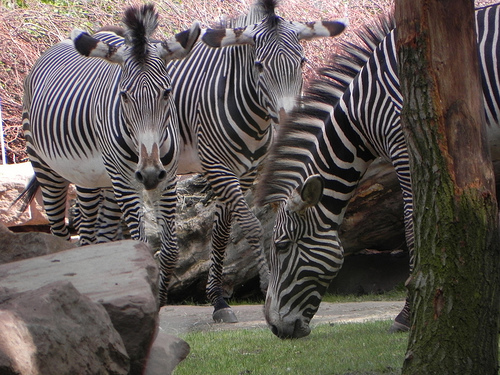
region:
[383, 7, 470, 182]
the trunk is sliced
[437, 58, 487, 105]
the trunk is sliced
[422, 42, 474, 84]
the trunk is sliced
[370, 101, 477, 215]
the trunk is sliced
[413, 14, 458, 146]
the trunk is sliced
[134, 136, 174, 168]
Brown markings on zebra's face.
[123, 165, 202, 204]
Zebra has black nose.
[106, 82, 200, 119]
Zebra has dark eyes.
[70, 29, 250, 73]
Zebra has black and white ears.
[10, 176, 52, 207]
Zebra has black hair on tail.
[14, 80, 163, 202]
Zebra is covered in stripes.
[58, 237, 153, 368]
Large gray rocks near zebras.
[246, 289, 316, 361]
Zebra is bending over to eat.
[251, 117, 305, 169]
Zebra has black and white hair on head.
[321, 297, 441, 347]
Zebra is standing in grass.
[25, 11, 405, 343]
Three zebras are in the picture.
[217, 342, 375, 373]
The grass is green.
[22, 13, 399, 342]
The zebras are black and white.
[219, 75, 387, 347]
The zebra is eating.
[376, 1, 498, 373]
A tree trunk.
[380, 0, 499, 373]
The tree trunk is brown.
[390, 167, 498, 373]
The tree trunk has moss on it.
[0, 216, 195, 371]
The rocks are gray.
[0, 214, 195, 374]
The rocks are large.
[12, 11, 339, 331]
Two zebras are walking.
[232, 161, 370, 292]
the zebra is eating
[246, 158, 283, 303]
the zebra is eating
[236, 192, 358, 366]
the zebra is eating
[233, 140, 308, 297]
the zebra is eating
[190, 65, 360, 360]
the zebra is eating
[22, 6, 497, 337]
three zebras in a park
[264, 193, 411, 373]
zebra eating grass in park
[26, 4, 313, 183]
two zebras walking forward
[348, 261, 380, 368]
grass and stone ground in park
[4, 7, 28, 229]
forest and stone background in park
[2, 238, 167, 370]
large stones in foreground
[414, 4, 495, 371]
large tree cut in half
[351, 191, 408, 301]
dark area under a stone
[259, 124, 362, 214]
zebra's mane as it bows down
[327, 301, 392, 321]
stone ground in park